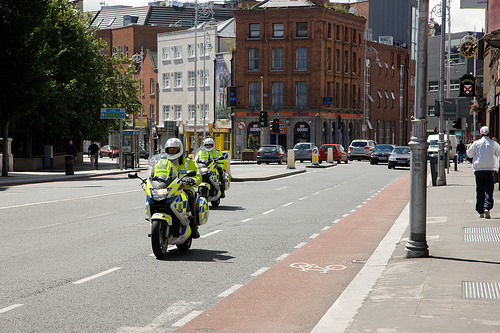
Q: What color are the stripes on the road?
A: White.